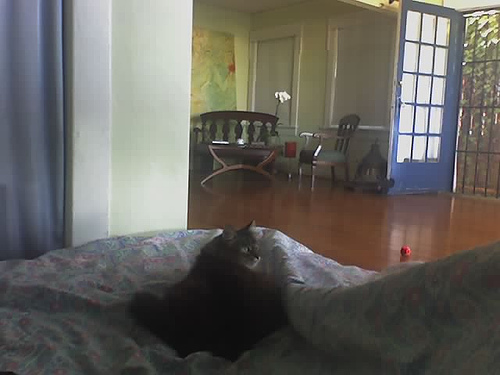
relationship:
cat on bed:
[120, 221, 290, 358] [11, 225, 496, 374]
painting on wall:
[187, 77, 247, 128] [146, 46, 177, 96]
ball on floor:
[396, 244, 414, 260] [190, 171, 492, 264]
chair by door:
[290, 138, 349, 202] [378, 123, 462, 208]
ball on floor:
[399, 245, 411, 256] [186, 167, 499, 273]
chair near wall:
[297, 114, 360, 193] [243, 91, 403, 206]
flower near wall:
[273, 80, 293, 117] [195, 64, 385, 194]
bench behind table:
[192, 104, 282, 165] [199, 127, 286, 200]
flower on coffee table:
[274, 90, 291, 103] [200, 142, 280, 185]